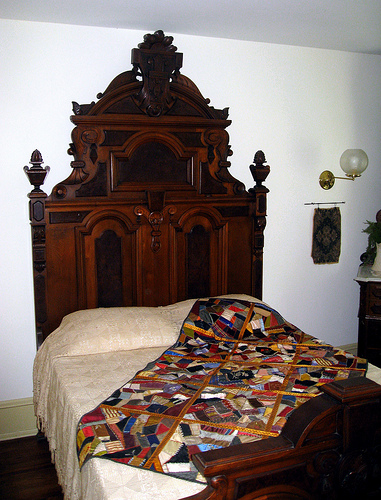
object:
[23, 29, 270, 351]
headboard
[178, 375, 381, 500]
footboard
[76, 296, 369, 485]
quilt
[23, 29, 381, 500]
bed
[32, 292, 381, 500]
bedspread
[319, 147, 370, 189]
wall lamp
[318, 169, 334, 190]
base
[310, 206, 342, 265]
material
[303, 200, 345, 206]
rod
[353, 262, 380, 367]
table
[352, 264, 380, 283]
top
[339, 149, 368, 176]
glass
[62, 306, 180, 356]
pillow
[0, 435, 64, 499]
carpet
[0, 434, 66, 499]
floor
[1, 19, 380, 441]
wall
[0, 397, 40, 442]
baseboard